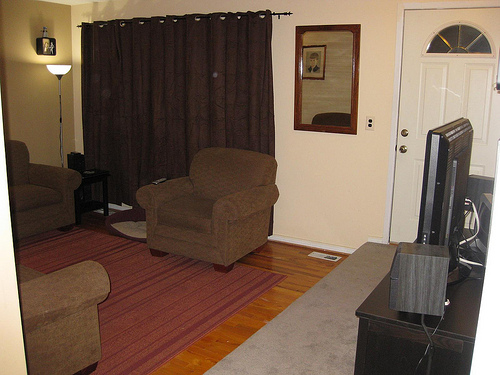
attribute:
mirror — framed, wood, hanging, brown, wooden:
[294, 18, 353, 160]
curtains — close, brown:
[71, 28, 241, 172]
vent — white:
[300, 242, 363, 271]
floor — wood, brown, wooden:
[268, 233, 345, 303]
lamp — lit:
[49, 58, 78, 162]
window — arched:
[431, 25, 497, 59]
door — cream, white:
[409, 19, 499, 151]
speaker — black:
[68, 146, 86, 175]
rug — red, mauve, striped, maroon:
[86, 242, 200, 339]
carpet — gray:
[279, 306, 359, 374]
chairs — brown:
[11, 157, 252, 261]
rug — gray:
[274, 300, 316, 369]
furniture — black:
[352, 299, 470, 372]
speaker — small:
[384, 229, 456, 326]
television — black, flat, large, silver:
[416, 115, 470, 245]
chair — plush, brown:
[153, 152, 262, 246]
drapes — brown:
[89, 36, 284, 159]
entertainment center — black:
[354, 265, 471, 373]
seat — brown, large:
[7, 141, 84, 238]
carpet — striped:
[147, 294, 237, 332]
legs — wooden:
[211, 257, 237, 277]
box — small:
[38, 32, 82, 65]